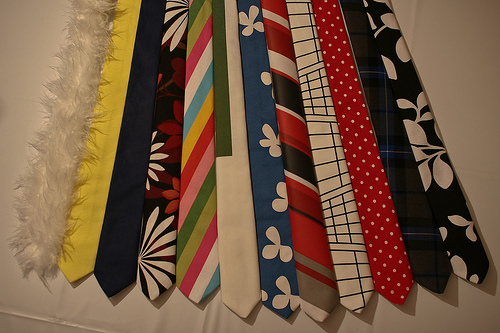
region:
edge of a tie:
[183, 283, 208, 303]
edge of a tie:
[236, 310, 251, 324]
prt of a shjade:
[108, 289, 132, 311]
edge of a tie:
[253, 288, 282, 323]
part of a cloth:
[229, 313, 244, 330]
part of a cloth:
[156, 300, 174, 316]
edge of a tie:
[231, 305, 247, 318]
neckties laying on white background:
[2, 19, 499, 330]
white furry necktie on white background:
[13, 3, 95, 285]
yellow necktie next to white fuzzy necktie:
[41, 8, 124, 290]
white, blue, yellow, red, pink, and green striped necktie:
[170, 18, 238, 303]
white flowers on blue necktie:
[234, 5, 329, 327]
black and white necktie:
[297, 57, 364, 256]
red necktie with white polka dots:
[323, 41, 417, 308]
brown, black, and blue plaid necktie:
[353, 36, 441, 245]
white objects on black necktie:
[375, 19, 484, 273]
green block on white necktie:
[207, 14, 261, 261]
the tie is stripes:
[260, 13, 330, 315]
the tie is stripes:
[177, 3, 208, 331]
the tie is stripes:
[180, 8, 236, 314]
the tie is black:
[123, 1, 153, 300]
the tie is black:
[346, 17, 430, 314]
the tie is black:
[96, 27, 174, 300]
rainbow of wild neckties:
[12, 230, 487, 301]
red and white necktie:
[340, 155, 395, 210]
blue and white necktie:
[250, 160, 290, 265]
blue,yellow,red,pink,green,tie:
[182, 116, 207, 212]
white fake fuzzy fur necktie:
[25, 156, 55, 252]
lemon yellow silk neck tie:
[75, 175, 95, 250]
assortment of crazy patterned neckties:
[10, 0, 491, 315]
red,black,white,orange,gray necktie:
[281, 145, 316, 256]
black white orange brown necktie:
[151, 110, 176, 225]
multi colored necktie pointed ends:
[5, 245, 495, 321]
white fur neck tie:
[16, 3, 115, 270]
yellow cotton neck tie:
[58, 2, 143, 280]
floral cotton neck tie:
[139, 0, 183, 309]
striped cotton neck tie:
[181, 0, 221, 308]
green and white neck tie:
[209, 2, 261, 317]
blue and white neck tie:
[236, 2, 301, 317]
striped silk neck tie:
[261, 2, 343, 325]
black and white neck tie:
[288, 1, 375, 316]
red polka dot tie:
[313, 3, 414, 305]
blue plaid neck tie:
[342, 1, 454, 296]